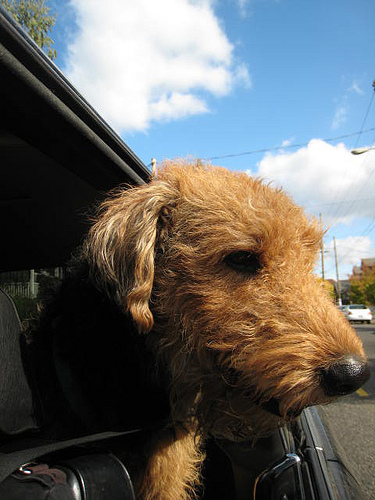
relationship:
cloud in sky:
[61, 1, 251, 138] [192, 11, 372, 146]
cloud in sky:
[61, 1, 251, 138] [67, 0, 372, 208]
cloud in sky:
[246, 138, 375, 224] [67, 0, 372, 208]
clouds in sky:
[315, 233, 373, 271] [67, 0, 372, 208]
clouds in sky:
[332, 68, 360, 128] [67, 0, 372, 208]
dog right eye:
[23, 154, 370, 498] [222, 246, 261, 272]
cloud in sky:
[255, 130, 373, 231] [8, 1, 371, 281]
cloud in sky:
[51, 1, 247, 125] [8, 1, 371, 281]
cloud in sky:
[61, 1, 251, 138] [49, 6, 373, 121]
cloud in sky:
[61, 1, 251, 138] [8, 1, 371, 281]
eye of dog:
[216, 242, 266, 275] [23, 154, 370, 498]